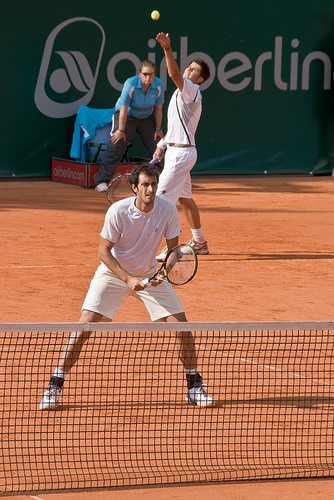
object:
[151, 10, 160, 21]
ball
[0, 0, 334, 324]
air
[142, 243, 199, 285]
raquet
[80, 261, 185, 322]
shorts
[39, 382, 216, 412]
sneakers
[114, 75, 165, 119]
shirt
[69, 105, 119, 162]
jacket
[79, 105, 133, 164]
chair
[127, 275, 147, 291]
hand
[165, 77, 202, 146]
shirt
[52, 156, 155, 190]
platform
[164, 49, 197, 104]
arm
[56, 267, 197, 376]
legs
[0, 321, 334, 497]
net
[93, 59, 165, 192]
person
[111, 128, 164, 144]
hands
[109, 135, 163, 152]
knees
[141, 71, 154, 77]
sunglasses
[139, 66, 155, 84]
face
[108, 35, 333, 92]
letters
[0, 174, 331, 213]
shadows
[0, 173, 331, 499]
court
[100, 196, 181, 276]
shirt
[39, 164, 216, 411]
player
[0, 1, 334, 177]
poster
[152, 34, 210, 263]
man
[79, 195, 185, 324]
clothes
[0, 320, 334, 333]
border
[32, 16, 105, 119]
logo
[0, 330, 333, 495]
string